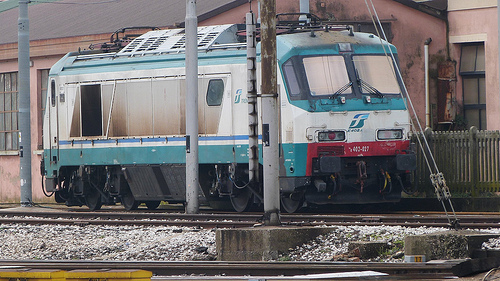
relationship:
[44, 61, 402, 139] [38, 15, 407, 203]
stripe on train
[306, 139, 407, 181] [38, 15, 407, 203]
stripe on train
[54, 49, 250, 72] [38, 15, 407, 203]
stripe on train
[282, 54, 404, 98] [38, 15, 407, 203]
windshield wipers on train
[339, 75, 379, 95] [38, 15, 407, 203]
windshield wipers on train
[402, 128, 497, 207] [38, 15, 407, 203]
fence next to train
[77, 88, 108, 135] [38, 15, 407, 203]
window on train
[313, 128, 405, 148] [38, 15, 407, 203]
lights on train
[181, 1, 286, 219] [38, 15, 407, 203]
poles next to train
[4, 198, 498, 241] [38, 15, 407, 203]
train tracks for train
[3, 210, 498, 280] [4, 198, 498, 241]
gravel around train tracks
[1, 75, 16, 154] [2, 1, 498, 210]
window on building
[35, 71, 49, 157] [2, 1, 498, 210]
window on a building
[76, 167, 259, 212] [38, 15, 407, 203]
wheels on train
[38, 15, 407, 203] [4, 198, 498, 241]
train on train tracks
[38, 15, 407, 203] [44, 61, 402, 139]
train has a stripe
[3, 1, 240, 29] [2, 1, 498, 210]
roof of building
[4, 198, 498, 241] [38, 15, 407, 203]
train tracks under train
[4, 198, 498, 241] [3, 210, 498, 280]
train tracks covered by gravel